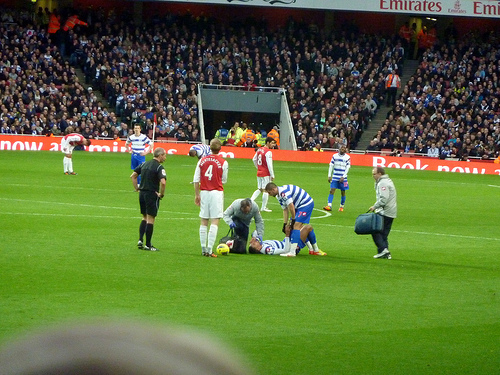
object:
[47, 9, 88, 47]
person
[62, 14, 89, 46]
person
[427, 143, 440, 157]
person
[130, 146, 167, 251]
player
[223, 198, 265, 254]
doctor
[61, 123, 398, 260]
players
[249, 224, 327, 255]
player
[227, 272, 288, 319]
floor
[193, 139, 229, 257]
soccer player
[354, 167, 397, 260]
doctor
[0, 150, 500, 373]
field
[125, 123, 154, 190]
player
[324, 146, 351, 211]
player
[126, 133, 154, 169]
uniform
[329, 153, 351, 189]
uniform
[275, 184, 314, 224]
uniform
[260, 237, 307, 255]
uniform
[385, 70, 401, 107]
man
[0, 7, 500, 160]
spectators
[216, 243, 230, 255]
soccer ball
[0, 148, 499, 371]
ground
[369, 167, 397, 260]
man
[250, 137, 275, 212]
team member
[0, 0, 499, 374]
arena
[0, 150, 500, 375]
grass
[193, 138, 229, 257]
member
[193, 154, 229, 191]
jersey number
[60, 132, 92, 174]
player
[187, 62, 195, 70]
spectator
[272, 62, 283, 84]
spectator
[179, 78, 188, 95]
spectator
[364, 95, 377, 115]
spectator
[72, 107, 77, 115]
spectator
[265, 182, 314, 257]
player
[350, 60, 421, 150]
stairs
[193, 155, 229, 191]
jersey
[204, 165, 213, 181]
number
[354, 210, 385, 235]
bag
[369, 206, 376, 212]
hand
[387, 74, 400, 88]
vest